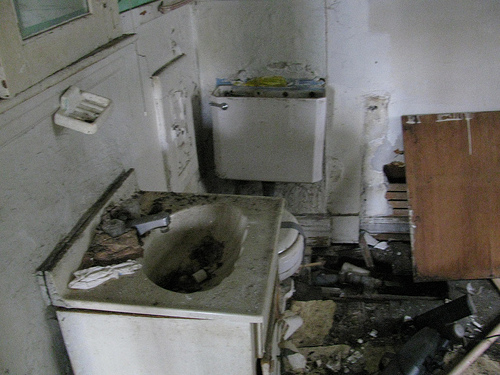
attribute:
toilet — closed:
[274, 206, 306, 270]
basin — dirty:
[44, 147, 316, 344]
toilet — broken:
[208, 66, 326, 298]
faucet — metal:
[125, 212, 168, 237]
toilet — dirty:
[266, 213, 309, 278]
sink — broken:
[81, 197, 304, 329]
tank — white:
[209, 84, 326, 185]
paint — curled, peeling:
[238, 301, 323, 373]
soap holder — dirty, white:
[39, 69, 154, 151]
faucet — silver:
[125, 211, 172, 235]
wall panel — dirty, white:
[152, 53, 199, 192]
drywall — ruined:
[330, 58, 411, 218]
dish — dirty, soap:
[53, 85, 111, 136]